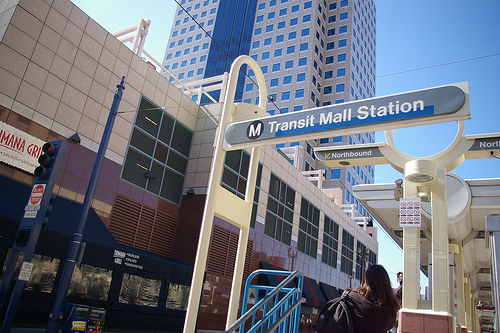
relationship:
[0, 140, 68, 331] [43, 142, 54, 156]
light indicates stop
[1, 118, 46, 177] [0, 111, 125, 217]
sign on wall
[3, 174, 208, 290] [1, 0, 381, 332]
awning on building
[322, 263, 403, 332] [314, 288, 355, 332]
woman has backpack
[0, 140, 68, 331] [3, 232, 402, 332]
signal for traffic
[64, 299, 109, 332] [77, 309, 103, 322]
boxes have newspapers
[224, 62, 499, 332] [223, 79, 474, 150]
subway has sign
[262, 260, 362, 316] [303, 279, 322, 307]
awning has stripes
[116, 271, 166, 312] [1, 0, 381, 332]
window on building